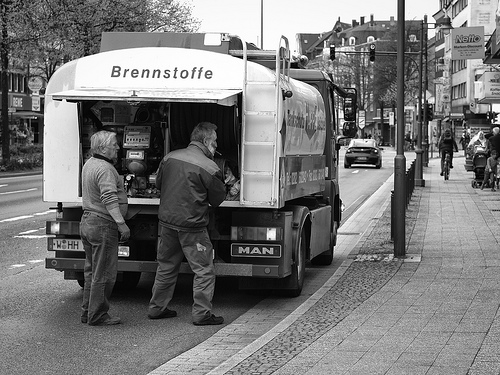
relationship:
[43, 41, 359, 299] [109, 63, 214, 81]
truck has logo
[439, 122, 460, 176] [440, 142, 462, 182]
person riding bike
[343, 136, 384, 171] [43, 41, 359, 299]
car in front of truck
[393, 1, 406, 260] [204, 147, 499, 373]
pole on sidewalk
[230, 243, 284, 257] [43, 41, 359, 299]
sign on truck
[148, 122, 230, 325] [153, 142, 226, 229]
man wearing jacket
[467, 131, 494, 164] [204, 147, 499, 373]
woman on sidewalk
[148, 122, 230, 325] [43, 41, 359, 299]
man behind truck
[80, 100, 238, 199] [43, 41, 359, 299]
goods in truck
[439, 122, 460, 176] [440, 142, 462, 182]
person on bike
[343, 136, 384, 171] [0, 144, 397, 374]
car on road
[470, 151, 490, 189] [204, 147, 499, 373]
stroller on sidewalk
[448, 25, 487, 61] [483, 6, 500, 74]
sign on building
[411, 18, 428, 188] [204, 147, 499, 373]
pole on sidewalk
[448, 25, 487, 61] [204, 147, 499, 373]
sign hanging over sidewalk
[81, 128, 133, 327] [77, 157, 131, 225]
old man wearing shirt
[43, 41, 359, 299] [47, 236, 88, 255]
truck has plate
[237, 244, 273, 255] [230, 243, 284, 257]
word on sign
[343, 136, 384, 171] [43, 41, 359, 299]
car before truck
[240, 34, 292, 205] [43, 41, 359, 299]
ladder on truck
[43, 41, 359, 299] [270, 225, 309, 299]
truck has back wheel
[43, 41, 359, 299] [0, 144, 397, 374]
truck on road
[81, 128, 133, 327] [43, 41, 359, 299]
old man behind truck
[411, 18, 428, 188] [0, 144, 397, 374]
pole near road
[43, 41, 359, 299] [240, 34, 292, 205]
truck has ladder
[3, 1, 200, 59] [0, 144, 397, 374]
tree near road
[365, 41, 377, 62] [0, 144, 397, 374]
traffic ligh over road